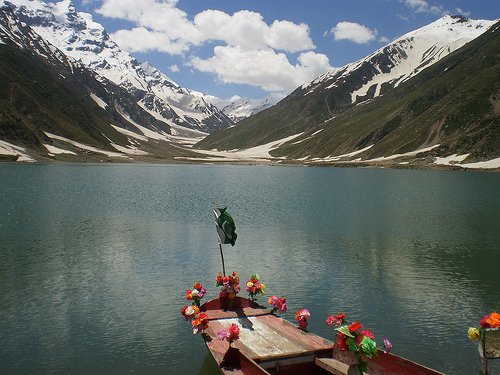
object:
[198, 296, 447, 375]
boat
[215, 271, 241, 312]
flowers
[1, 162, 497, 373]
lake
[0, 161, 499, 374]
water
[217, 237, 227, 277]
pole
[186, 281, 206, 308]
bouquet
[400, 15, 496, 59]
snow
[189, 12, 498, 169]
mountain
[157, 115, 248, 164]
valley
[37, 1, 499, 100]
sky